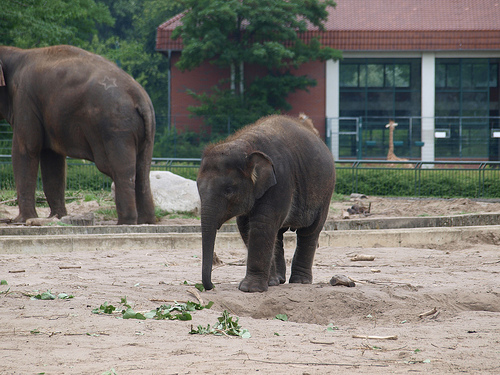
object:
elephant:
[0, 45, 157, 226]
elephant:
[196, 113, 336, 293]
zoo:
[0, 161, 500, 375]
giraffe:
[385, 120, 414, 168]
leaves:
[0, 280, 251, 340]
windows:
[338, 53, 420, 163]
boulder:
[111, 170, 201, 216]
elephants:
[0, 44, 335, 293]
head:
[197, 144, 255, 291]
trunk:
[200, 197, 219, 291]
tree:
[173, 0, 344, 160]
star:
[100, 76, 118, 90]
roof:
[154, 0, 499, 51]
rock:
[330, 275, 356, 287]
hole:
[208, 286, 402, 329]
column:
[326, 56, 340, 164]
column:
[420, 55, 437, 169]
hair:
[204, 114, 303, 156]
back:
[23, 47, 155, 169]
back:
[234, 115, 335, 199]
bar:
[155, 0, 499, 168]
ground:
[0, 240, 498, 375]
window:
[438, 59, 497, 160]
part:
[489, 61, 498, 86]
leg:
[41, 157, 67, 219]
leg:
[133, 160, 156, 224]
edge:
[147, 181, 157, 223]